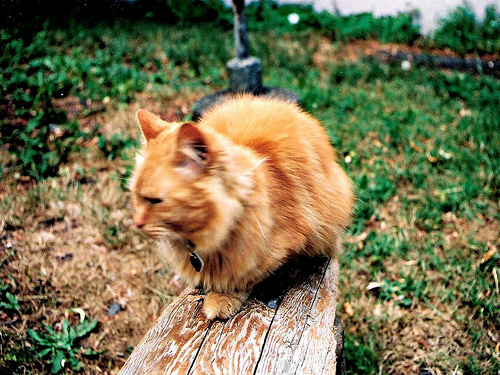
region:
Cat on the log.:
[80, 73, 434, 373]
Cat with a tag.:
[138, 185, 243, 285]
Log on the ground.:
[94, 259, 265, 369]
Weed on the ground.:
[20, 303, 103, 373]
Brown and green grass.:
[342, 227, 490, 355]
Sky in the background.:
[289, 0, 485, 73]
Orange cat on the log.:
[87, 37, 469, 345]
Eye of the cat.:
[138, 151, 188, 221]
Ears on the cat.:
[101, 90, 302, 202]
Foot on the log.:
[192, 267, 269, 324]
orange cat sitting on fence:
[110, 97, 357, 318]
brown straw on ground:
[393, 316, 450, 350]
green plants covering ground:
[366, 70, 473, 169]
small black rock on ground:
[95, 290, 130, 320]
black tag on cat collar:
[180, 245, 205, 280]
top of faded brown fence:
[150, 323, 298, 373]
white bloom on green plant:
[273, 2, 320, 36]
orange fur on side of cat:
[270, 152, 327, 212]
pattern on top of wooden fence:
[208, 335, 253, 373]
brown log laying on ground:
[370, 47, 498, 80]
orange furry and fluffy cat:
[191, 111, 327, 271]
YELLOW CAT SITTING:
[132, 86, 351, 320]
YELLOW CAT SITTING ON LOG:
[115, 243, 340, 373]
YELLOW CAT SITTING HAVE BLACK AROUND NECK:
[180, 236, 207, 273]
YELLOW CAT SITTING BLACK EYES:
[134, 197, 164, 208]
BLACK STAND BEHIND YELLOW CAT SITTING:
[179, 1, 304, 129]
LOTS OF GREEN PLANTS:
[2, 2, 496, 369]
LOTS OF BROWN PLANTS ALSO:
[0, 43, 497, 370]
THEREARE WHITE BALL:
[284, 12, 300, 24]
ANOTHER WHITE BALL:
[397, 56, 419, 78]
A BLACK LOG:
[389, 44, 499, 73]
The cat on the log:
[122, 75, 373, 326]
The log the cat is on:
[95, 244, 355, 373]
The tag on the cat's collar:
[189, 251, 206, 278]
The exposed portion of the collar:
[181, 238, 197, 255]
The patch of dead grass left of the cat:
[4, 168, 186, 366]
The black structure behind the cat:
[181, 0, 317, 125]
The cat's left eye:
[140, 185, 165, 212]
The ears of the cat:
[132, 105, 216, 170]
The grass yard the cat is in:
[1, 21, 496, 373]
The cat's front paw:
[199, 277, 244, 330]